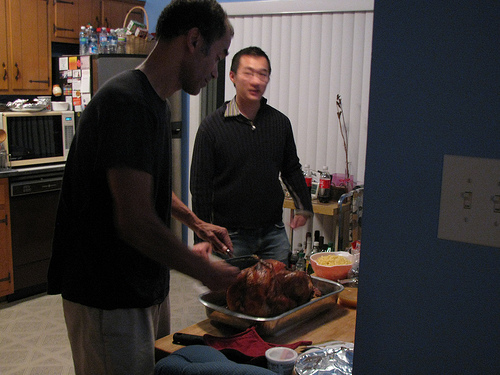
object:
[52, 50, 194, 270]
refrigerator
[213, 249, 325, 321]
chicken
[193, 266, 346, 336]
tray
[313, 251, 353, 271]
food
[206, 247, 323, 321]
food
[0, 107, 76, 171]
microwave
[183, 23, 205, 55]
ear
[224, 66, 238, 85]
ear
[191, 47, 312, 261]
man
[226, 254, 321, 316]
turkey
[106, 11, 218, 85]
basket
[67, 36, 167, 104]
fridge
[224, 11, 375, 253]
blinds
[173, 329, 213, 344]
handle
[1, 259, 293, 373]
floor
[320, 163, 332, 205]
bottle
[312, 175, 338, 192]
red label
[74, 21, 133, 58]
bottles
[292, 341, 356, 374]
aluminum paper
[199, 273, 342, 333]
pan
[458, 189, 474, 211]
switch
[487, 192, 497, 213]
switch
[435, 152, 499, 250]
panel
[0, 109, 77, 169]
microwave oven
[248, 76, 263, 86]
nose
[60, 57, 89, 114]
notes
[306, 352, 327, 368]
foil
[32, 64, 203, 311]
shirt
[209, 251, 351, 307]
turkey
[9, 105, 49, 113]
dish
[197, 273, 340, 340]
pan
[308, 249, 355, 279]
bowl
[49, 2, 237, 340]
man